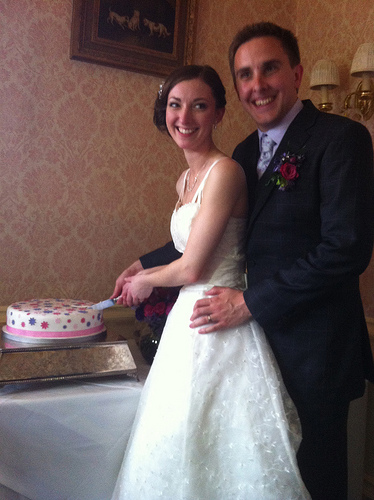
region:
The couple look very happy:
[36, 15, 370, 455]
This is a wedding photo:
[35, 20, 368, 422]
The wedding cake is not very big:
[4, 267, 118, 358]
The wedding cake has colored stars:
[4, 281, 111, 345]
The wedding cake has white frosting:
[5, 292, 112, 361]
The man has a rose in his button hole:
[262, 144, 310, 197]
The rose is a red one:
[265, 147, 312, 205]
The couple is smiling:
[84, 18, 334, 147]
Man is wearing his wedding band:
[192, 301, 224, 333]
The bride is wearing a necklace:
[168, 150, 237, 198]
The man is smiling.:
[223, 13, 308, 149]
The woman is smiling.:
[129, 62, 232, 180]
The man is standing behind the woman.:
[108, 13, 372, 498]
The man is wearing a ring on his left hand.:
[95, 13, 372, 498]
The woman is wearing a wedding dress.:
[112, 9, 372, 497]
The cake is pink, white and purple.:
[0, 269, 119, 349]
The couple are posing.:
[4, 19, 373, 498]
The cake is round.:
[1, 280, 114, 361]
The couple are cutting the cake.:
[1, 11, 373, 360]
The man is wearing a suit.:
[107, 19, 372, 497]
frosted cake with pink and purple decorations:
[4, 296, 107, 340]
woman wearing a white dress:
[109, 64, 307, 497]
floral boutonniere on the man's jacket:
[272, 151, 304, 190]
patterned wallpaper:
[12, 76, 142, 248]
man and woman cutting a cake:
[87, 34, 353, 332]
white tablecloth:
[7, 388, 116, 479]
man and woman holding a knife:
[94, 273, 138, 312]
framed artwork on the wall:
[66, 0, 192, 69]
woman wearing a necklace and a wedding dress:
[115, 65, 277, 498]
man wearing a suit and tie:
[192, 18, 372, 497]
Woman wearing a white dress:
[111, 60, 309, 498]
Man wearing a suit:
[110, 20, 372, 499]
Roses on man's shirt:
[262, 146, 313, 197]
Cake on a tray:
[1, 288, 110, 345]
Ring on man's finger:
[200, 312, 219, 328]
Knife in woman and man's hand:
[85, 257, 152, 317]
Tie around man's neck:
[254, 126, 279, 182]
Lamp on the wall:
[305, 44, 373, 120]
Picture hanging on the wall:
[61, 5, 208, 81]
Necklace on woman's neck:
[179, 160, 215, 194]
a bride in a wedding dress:
[112, 60, 310, 499]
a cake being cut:
[8, 289, 119, 342]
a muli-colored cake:
[9, 294, 103, 344]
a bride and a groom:
[113, 22, 368, 498]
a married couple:
[110, 24, 372, 498]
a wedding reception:
[3, 23, 366, 499]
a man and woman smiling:
[110, 15, 372, 498]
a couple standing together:
[110, 19, 370, 498]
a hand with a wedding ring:
[188, 284, 254, 340]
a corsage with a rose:
[270, 149, 306, 194]